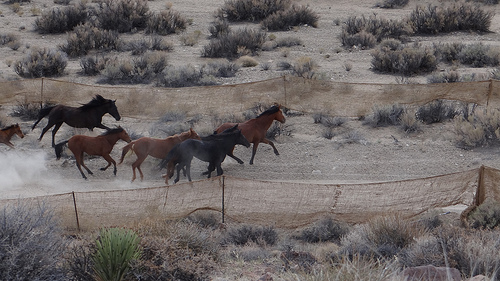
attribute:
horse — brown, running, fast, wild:
[3, 117, 24, 152]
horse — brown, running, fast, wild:
[19, 90, 131, 126]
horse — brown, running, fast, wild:
[52, 121, 126, 181]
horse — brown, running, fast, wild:
[134, 127, 199, 178]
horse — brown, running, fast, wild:
[171, 124, 255, 179]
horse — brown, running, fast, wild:
[248, 108, 293, 163]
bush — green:
[18, 51, 60, 77]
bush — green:
[35, 4, 82, 30]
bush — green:
[63, 26, 132, 51]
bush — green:
[105, 51, 158, 79]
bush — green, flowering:
[200, 27, 265, 62]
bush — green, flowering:
[267, 2, 315, 31]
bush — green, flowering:
[334, 7, 406, 47]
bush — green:
[366, 39, 445, 73]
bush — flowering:
[96, 230, 141, 273]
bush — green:
[148, 225, 205, 261]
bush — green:
[239, 217, 278, 245]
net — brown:
[157, 87, 193, 96]